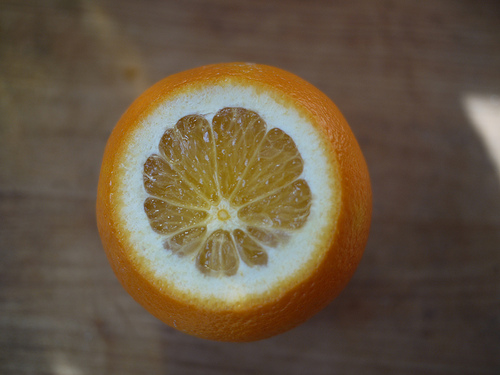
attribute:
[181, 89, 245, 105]
skin — white, textured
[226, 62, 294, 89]
skin — orange, textured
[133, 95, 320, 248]
inside — fruit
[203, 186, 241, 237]
inner core — white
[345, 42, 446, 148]
table — here, wooden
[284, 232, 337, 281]
rind — white